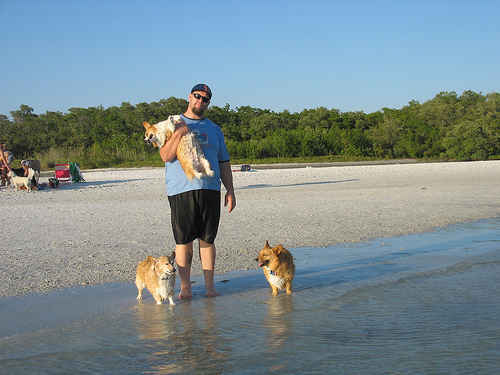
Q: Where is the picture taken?
A: Beach.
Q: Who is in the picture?
A: A man.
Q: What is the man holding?
A: A dog.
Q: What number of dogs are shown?
A: Three.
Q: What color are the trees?
A: Green.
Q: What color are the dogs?
A: Brown and white.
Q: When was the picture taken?
A: Daytime.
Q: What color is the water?
A: Gray and blue.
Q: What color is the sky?
A: Blue.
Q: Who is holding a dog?
A: The man.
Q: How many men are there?
A: One.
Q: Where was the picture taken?
A: On the beach.